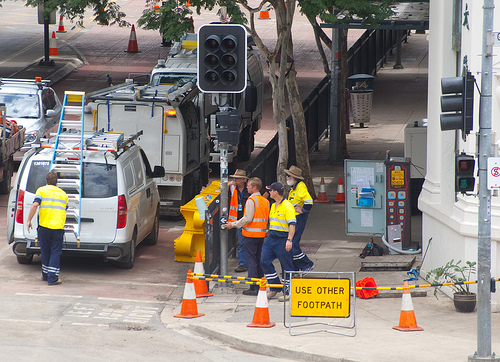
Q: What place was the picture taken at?
A: It was taken at the road.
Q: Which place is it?
A: It is a road.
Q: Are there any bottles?
A: No, there are no bottles.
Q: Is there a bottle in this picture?
A: No, there are no bottles.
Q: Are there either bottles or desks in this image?
A: No, there are no bottles or desks.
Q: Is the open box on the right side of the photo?
A: Yes, the box is on the right of the image.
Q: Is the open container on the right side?
A: Yes, the box is on the right of the image.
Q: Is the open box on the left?
A: No, the box is on the right of the image.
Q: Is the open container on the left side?
A: No, the box is on the right of the image.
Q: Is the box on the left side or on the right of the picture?
A: The box is on the right of the image.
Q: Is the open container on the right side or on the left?
A: The box is on the right of the image.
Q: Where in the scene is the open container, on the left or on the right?
A: The box is on the right of the image.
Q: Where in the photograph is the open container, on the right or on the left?
A: The box is on the right of the image.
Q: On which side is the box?
A: The box is on the right of the image.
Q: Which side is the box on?
A: The box is on the right of the image.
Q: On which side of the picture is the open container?
A: The box is on the right of the image.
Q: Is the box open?
A: Yes, the box is open.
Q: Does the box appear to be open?
A: Yes, the box is open.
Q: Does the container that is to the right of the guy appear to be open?
A: Yes, the box is open.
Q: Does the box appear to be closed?
A: No, the box is open.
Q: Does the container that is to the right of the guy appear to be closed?
A: No, the box is open.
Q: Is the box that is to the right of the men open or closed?
A: The box is open.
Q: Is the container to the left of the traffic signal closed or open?
A: The box is open.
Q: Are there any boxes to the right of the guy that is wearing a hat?
A: Yes, there is a box to the right of the guy.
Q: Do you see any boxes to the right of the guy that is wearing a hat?
A: Yes, there is a box to the right of the guy.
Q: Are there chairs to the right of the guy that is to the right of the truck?
A: No, there is a box to the right of the guy.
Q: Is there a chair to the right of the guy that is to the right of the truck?
A: No, there is a box to the right of the guy.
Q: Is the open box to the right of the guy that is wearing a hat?
A: Yes, the box is to the right of the guy.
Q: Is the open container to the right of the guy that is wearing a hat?
A: Yes, the box is to the right of the guy.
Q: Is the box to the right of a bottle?
A: No, the box is to the right of the guy.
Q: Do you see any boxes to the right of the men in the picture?
A: Yes, there is a box to the right of the men.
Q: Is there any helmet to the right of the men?
A: No, there is a box to the right of the men.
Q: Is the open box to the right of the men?
A: Yes, the box is to the right of the men.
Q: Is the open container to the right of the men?
A: Yes, the box is to the right of the men.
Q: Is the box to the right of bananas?
A: No, the box is to the right of the men.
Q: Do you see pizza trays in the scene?
A: No, there are no pizza trays.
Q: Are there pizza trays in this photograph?
A: No, there are no pizza trays.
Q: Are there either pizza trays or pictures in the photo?
A: No, there are no pizza trays or pictures.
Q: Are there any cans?
A: Yes, there is a can.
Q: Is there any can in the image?
A: Yes, there is a can.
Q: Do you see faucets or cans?
A: Yes, there is a can.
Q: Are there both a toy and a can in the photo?
A: No, there is a can but no toys.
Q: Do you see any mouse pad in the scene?
A: No, there are no mouse pads.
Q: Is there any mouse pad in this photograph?
A: No, there are no mouse pads.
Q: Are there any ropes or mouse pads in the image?
A: No, there are no mouse pads or ropes.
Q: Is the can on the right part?
A: Yes, the can is on the right of the image.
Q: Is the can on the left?
A: No, the can is on the right of the image.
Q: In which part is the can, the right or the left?
A: The can is on the right of the image.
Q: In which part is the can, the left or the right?
A: The can is on the right of the image.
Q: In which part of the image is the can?
A: The can is on the right of the image.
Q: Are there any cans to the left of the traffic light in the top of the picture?
A: Yes, there is a can to the left of the signal light.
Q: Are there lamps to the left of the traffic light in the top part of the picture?
A: No, there is a can to the left of the signal light.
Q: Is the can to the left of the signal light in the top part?
A: Yes, the can is to the left of the traffic light.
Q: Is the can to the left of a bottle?
A: No, the can is to the left of the traffic light.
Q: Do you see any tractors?
A: No, there are no tractors.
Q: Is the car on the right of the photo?
A: No, the car is on the left of the image.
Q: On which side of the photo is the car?
A: The car is on the left of the image.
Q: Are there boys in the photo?
A: No, there are no boys.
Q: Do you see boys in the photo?
A: No, there are no boys.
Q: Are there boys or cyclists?
A: No, there are no boys or cyclists.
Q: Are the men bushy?
A: Yes, the men are bushy.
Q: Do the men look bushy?
A: Yes, the men are bushy.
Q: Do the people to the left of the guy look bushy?
A: Yes, the men are bushy.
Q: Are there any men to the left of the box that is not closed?
A: Yes, there are men to the left of the box.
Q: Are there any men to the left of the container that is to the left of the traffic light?
A: Yes, there are men to the left of the box.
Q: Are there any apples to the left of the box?
A: No, there are men to the left of the box.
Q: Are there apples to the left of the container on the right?
A: No, there are men to the left of the box.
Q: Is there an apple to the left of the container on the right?
A: No, there are men to the left of the box.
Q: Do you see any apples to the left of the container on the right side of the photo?
A: No, there are men to the left of the box.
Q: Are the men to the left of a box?
A: Yes, the men are to the left of a box.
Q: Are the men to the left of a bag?
A: No, the men are to the left of a box.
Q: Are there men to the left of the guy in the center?
A: Yes, there are men to the left of the guy.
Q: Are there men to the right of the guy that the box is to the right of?
A: No, the men are to the left of the guy.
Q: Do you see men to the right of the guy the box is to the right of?
A: No, the men are to the left of the guy.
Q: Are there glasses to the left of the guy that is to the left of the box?
A: No, there are men to the left of the guy.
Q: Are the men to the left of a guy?
A: Yes, the men are to the left of a guy.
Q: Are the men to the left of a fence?
A: No, the men are to the left of a guy.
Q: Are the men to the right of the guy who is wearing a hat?
A: No, the men are to the left of the guy.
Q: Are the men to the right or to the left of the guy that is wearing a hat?
A: The men are to the left of the guy.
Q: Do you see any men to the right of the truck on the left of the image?
A: Yes, there are men to the right of the truck.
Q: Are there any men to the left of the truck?
A: No, the men are to the right of the truck.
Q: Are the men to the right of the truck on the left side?
A: Yes, the men are to the right of the truck.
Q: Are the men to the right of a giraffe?
A: No, the men are to the right of the truck.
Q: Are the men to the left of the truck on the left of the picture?
A: No, the men are to the right of the truck.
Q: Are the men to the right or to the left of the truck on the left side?
A: The men are to the right of the truck.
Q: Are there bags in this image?
A: No, there are no bags.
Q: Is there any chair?
A: No, there are no chairs.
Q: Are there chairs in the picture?
A: No, there are no chairs.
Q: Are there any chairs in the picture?
A: No, there are no chairs.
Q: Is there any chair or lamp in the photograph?
A: No, there are no chairs or lamps.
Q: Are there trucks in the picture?
A: Yes, there is a truck.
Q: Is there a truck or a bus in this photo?
A: Yes, there is a truck.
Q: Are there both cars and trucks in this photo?
A: Yes, there are both a truck and cars.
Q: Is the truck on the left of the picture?
A: Yes, the truck is on the left of the image.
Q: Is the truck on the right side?
A: No, the truck is on the left of the image.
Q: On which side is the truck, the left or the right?
A: The truck is on the left of the image.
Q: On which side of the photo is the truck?
A: The truck is on the left of the image.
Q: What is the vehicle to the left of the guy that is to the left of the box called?
A: The vehicle is a truck.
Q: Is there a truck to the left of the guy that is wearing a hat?
A: Yes, there is a truck to the left of the guy.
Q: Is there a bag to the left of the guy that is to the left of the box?
A: No, there is a truck to the left of the guy.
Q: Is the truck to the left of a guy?
A: Yes, the truck is to the left of a guy.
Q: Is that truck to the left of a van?
A: No, the truck is to the left of a guy.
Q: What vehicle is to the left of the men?
A: The vehicle is a truck.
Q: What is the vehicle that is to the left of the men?
A: The vehicle is a truck.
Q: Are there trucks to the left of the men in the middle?
A: Yes, there is a truck to the left of the men.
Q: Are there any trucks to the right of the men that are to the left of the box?
A: No, the truck is to the left of the men.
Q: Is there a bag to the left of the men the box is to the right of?
A: No, there is a truck to the left of the men.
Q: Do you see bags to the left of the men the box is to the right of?
A: No, there is a truck to the left of the men.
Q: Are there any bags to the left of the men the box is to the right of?
A: No, there is a truck to the left of the men.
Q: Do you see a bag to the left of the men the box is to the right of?
A: No, there is a truck to the left of the men.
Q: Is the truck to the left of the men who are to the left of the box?
A: Yes, the truck is to the left of the men.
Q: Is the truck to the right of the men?
A: No, the truck is to the left of the men.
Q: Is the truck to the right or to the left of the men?
A: The truck is to the left of the men.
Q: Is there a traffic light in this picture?
A: Yes, there is a traffic light.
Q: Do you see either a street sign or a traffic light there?
A: Yes, there is a traffic light.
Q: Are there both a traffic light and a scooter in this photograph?
A: No, there is a traffic light but no scooters.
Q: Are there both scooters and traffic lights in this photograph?
A: No, there is a traffic light but no scooters.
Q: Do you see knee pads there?
A: No, there are no knee pads.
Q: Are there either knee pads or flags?
A: No, there are no knee pads or flags.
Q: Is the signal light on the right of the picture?
A: Yes, the signal light is on the right of the image.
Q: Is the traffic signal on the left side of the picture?
A: No, the traffic signal is on the right of the image.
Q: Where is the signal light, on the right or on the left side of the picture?
A: The signal light is on the right of the image.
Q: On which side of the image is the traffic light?
A: The traffic light is on the right of the image.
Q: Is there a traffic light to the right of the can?
A: Yes, there is a traffic light to the right of the can.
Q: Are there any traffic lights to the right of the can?
A: Yes, there is a traffic light to the right of the can.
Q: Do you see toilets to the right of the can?
A: No, there is a traffic light to the right of the can.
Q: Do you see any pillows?
A: No, there are no pillows.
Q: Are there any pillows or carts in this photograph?
A: No, there are no pillows or carts.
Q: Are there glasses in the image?
A: No, there are no glasses.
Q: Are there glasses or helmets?
A: No, there are no glasses or helmets.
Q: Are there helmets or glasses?
A: No, there are no glasses or helmets.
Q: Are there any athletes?
A: No, there are no athletes.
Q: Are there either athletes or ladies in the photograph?
A: No, there are no athletes or ladies.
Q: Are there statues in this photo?
A: No, there are no statues.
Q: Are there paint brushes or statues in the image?
A: No, there are no statues or paint brushes.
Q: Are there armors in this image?
A: No, there are no armors.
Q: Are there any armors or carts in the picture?
A: No, there are no armors or carts.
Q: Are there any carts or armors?
A: No, there are no armors or carts.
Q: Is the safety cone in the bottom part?
A: Yes, the safety cone is in the bottom of the image.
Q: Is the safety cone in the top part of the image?
A: No, the safety cone is in the bottom of the image.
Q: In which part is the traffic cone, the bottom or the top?
A: The traffic cone is in the bottom of the image.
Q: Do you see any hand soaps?
A: No, there are no hand soaps.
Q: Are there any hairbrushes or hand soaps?
A: No, there are no hand soaps or hairbrushes.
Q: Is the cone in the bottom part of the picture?
A: Yes, the cone is in the bottom of the image.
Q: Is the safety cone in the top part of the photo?
A: No, the safety cone is in the bottom of the image.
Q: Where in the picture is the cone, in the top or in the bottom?
A: The cone is in the bottom of the image.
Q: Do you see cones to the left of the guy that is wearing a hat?
A: Yes, there is a cone to the left of the guy.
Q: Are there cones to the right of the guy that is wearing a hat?
A: No, the cone is to the left of the guy.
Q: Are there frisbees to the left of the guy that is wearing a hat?
A: No, there is a cone to the left of the guy.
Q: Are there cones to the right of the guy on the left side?
A: Yes, there is a cone to the right of the guy.